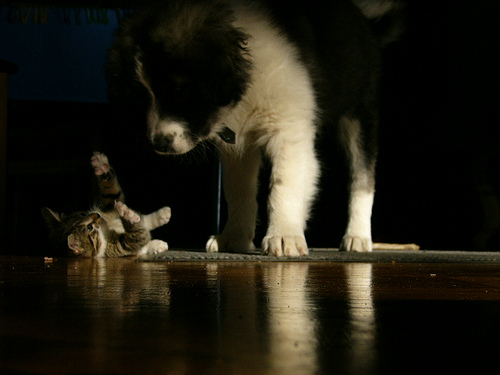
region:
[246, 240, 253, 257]
the rug is gray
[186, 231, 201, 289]
the rug is gray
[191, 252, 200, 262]
the rug is gray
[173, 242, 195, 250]
the rug is gray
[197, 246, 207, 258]
the rug is gray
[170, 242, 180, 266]
the rug is gray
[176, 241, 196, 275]
the rug is gray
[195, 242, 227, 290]
the rug is gray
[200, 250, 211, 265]
the rug is gray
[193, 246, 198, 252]
the rug is gray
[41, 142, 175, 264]
A Kitten at play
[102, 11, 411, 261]
A dog is looking down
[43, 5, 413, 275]
Dog and kitten are playing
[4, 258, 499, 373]
Hardwood floors reflect animals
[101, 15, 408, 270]
The dog is white and black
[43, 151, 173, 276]
The kitten is grey white and black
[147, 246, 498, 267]
Carpet is on top of wood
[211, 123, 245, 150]
Dog's tags dangle from neck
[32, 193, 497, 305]
Sunlight shines through window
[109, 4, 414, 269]
Dog is long hair breed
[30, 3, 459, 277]
two animals playing with each other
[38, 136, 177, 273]
kitten playing with dog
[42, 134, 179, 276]
kitten laying on ground with paws in the air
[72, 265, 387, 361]
reflection of animals on the floor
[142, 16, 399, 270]
black and white dog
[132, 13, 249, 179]
dog looking at playful kitten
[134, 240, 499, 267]
grey run the dog is standing on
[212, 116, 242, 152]
black collar around dogs neck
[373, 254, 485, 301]
dust on the hard wood floor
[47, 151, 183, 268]
brown and white kitten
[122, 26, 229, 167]
head of a small fluffy dog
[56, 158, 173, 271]
small kitten laying on the ground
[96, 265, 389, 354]
brown wooden floors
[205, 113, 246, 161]
collar around the dogs neck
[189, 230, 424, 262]
grey rung on top of the wood floor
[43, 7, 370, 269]
cat and dog playing with each other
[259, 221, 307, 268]
paw of a dog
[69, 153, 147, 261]
extended kitten legs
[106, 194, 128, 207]
claw of a kitten extended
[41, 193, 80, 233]
perked up ear of a kitten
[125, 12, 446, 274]
a white and black dog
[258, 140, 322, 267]
left leg of dog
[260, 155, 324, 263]
left dog is white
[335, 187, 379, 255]
back leg is white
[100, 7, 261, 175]
head of dog is black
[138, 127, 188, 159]
nose of black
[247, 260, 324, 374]
white front leg reflected on the floor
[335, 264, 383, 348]
back leg reflected on floor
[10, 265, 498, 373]
floor is shine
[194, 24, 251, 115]
ear of dog is black